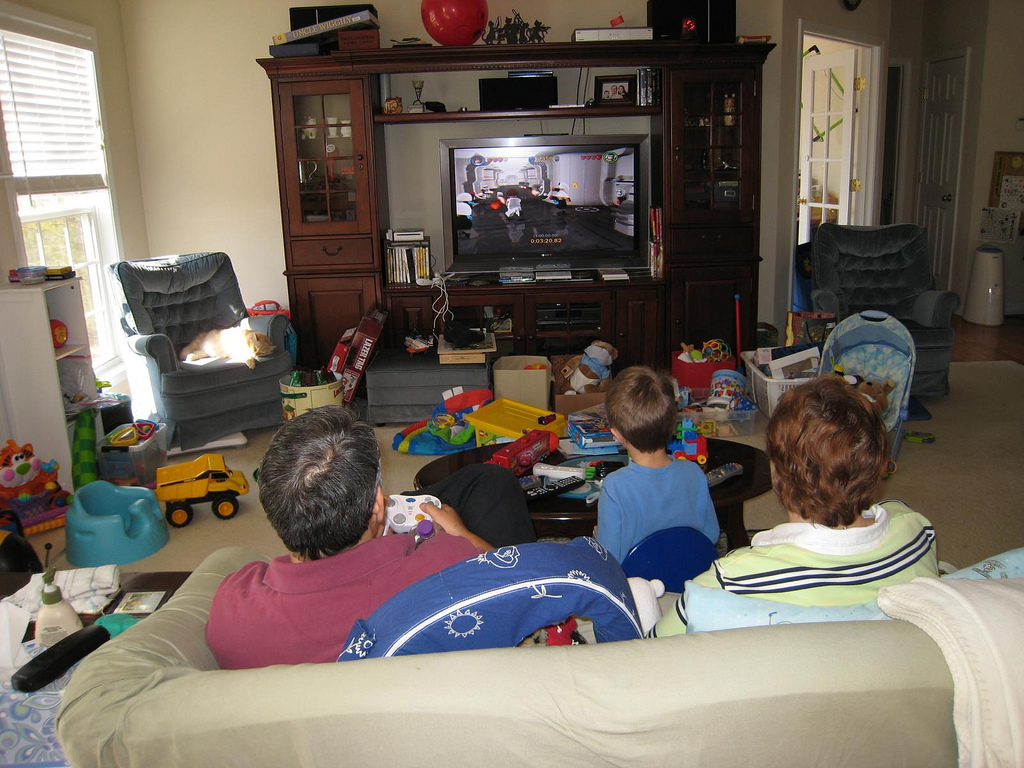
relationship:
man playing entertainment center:
[203, 404, 535, 670] [440, 134, 650, 272]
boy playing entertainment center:
[592, 364, 720, 565] [440, 134, 650, 272]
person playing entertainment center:
[686, 365, 947, 601] [440, 134, 650, 272]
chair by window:
[110, 250, 294, 451] [1, 17, 135, 376]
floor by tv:
[0, 307, 1024, 571] [431, 123, 641, 276]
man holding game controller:
[203, 404, 535, 670] [376, 478, 447, 532]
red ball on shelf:
[417, 0, 501, 54] [249, 49, 777, 360]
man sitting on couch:
[211, 411, 494, 669] [53, 534, 1021, 765]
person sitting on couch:
[643, 373, 939, 639] [53, 534, 1021, 765]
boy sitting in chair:
[584, 361, 724, 567] [619, 529, 714, 574]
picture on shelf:
[592, 74, 644, 104] [366, 93, 655, 119]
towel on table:
[55, 566, 119, 605] [44, 550, 199, 624]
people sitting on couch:
[52, 372, 1017, 762] [47, 545, 1021, 768]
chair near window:
[8, 12, 288, 449] [8, 31, 153, 401]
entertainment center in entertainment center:
[440, 134, 650, 272] [259, 24, 795, 362]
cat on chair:
[108, 243, 287, 449] [108, 243, 287, 449]